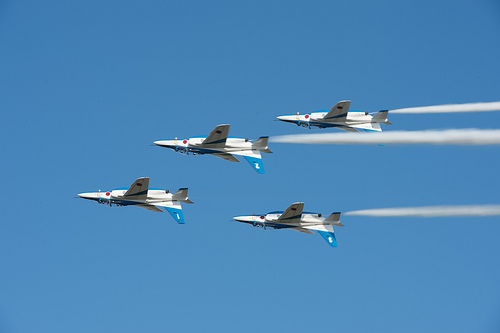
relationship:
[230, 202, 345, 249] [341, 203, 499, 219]
airplane with smoke trail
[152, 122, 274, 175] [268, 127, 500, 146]
airplane with smoke trail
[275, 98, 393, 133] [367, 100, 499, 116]
airplane with smoke trail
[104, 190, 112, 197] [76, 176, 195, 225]
dot on airplane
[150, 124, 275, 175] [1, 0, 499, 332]
airplane in sky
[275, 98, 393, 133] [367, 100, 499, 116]
airplane releasing smoke trail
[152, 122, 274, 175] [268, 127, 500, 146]
airplane releasing smoke trail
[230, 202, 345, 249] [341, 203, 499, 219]
airplane releasing smoke trail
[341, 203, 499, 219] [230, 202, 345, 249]
smoke trail coming from airplane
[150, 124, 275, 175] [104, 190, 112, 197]
airplane have dot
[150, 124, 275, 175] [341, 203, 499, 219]
airplane leaving smoke trail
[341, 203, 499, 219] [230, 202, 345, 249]
smoke trail from airplane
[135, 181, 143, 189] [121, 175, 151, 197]
circle on wing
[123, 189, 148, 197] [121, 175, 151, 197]
stripe on wing